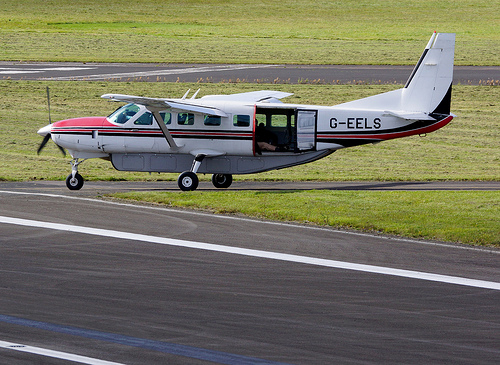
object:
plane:
[37, 33, 468, 186]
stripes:
[50, 111, 450, 138]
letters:
[329, 117, 382, 129]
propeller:
[30, 86, 66, 156]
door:
[254, 107, 298, 154]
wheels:
[66, 173, 85, 191]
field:
[0, 0, 500, 365]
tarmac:
[0, 207, 497, 364]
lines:
[0, 211, 500, 294]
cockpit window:
[113, 104, 141, 123]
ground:
[22, 175, 499, 216]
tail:
[393, 33, 460, 141]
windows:
[134, 111, 154, 126]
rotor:
[37, 123, 51, 136]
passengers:
[255, 118, 288, 152]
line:
[0, 317, 172, 365]